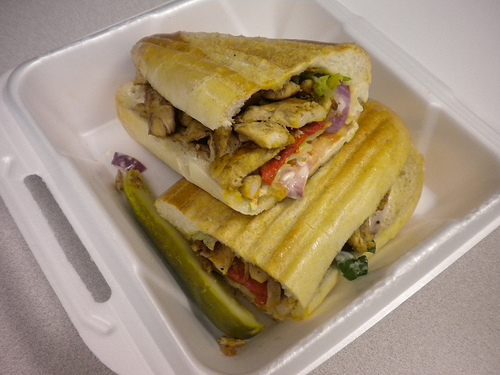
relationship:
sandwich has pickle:
[114, 32, 368, 214] [117, 167, 264, 350]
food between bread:
[211, 77, 347, 201] [131, 32, 369, 126]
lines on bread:
[142, 31, 277, 77] [131, 32, 369, 126]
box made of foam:
[33, 5, 498, 374] [1, 66, 120, 325]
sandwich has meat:
[114, 32, 368, 214] [242, 96, 327, 147]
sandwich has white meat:
[114, 32, 368, 214] [242, 96, 327, 147]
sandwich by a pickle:
[114, 32, 368, 214] [117, 167, 264, 350]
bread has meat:
[131, 32, 369, 126] [242, 96, 327, 147]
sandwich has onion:
[114, 32, 368, 214] [279, 84, 355, 196]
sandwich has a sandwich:
[114, 32, 368, 214] [114, 31, 371, 214]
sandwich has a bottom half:
[114, 32, 368, 214] [151, 94, 425, 323]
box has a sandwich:
[33, 5, 498, 374] [114, 32, 368, 214]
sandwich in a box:
[114, 32, 368, 214] [33, 5, 498, 374]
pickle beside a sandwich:
[117, 167, 264, 350] [114, 32, 368, 214]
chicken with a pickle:
[241, 85, 326, 145] [117, 167, 264, 350]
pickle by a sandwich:
[117, 167, 264, 350] [114, 32, 368, 214]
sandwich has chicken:
[114, 32, 368, 214] [241, 85, 326, 145]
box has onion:
[33, 5, 498, 374] [279, 84, 355, 196]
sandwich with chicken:
[114, 32, 368, 214] [241, 85, 326, 145]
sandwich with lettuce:
[114, 32, 368, 214] [336, 246, 369, 281]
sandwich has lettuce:
[114, 32, 368, 214] [336, 246, 369, 281]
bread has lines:
[131, 32, 369, 126] [142, 31, 277, 77]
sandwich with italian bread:
[114, 32, 368, 214] [131, 32, 369, 126]